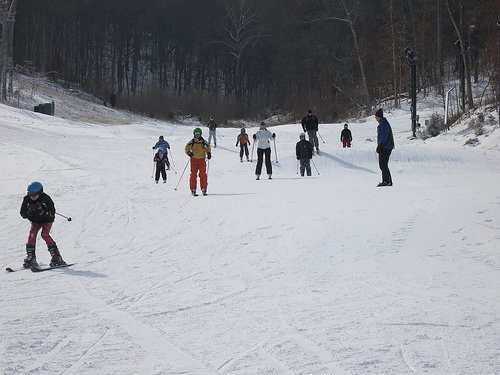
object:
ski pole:
[172, 155, 196, 190]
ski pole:
[270, 133, 280, 166]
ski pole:
[54, 203, 74, 223]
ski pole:
[171, 150, 193, 197]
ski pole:
[245, 131, 256, 165]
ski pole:
[315, 125, 325, 149]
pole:
[264, 134, 284, 165]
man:
[374, 107, 394, 185]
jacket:
[376, 117, 394, 151]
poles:
[243, 134, 261, 159]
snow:
[0, 85, 500, 375]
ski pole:
[304, 154, 326, 182]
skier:
[191, 136, 226, 189]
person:
[19, 182, 64, 265]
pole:
[41, 203, 72, 223]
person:
[289, 130, 324, 177]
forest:
[40, 16, 459, 139]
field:
[0, 122, 500, 375]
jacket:
[296, 138, 315, 163]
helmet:
[25, 179, 44, 197]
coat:
[183, 134, 217, 164]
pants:
[186, 152, 209, 193]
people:
[0, 99, 402, 274]